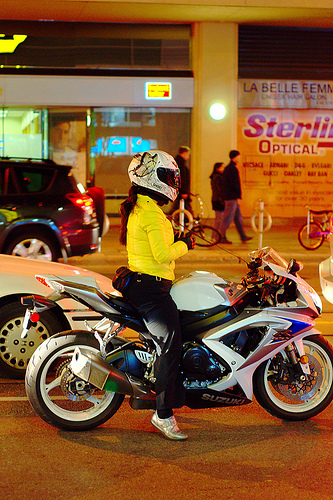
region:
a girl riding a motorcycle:
[96, 140, 233, 446]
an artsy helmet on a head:
[125, 146, 181, 199]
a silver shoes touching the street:
[145, 406, 193, 444]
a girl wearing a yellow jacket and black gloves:
[103, 144, 191, 445]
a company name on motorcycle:
[205, 390, 244, 407]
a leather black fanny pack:
[104, 266, 141, 290]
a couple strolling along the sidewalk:
[208, 141, 239, 237]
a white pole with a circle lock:
[254, 201, 273, 251]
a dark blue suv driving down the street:
[17, 157, 91, 254]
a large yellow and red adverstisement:
[243, 112, 322, 205]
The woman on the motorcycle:
[115, 149, 197, 440]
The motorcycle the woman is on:
[17, 244, 332, 432]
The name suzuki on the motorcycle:
[199, 389, 245, 408]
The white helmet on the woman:
[126, 147, 182, 202]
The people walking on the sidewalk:
[169, 143, 255, 247]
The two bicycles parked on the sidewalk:
[168, 193, 332, 249]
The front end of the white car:
[0, 249, 127, 378]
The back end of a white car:
[314, 223, 332, 306]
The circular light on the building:
[206, 102, 229, 120]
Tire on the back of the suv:
[86, 187, 109, 237]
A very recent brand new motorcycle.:
[18, 243, 332, 435]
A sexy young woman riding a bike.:
[111, 148, 195, 441]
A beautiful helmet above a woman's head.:
[126, 148, 181, 202]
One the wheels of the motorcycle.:
[24, 328, 129, 434]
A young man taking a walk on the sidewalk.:
[215, 147, 254, 244]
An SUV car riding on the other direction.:
[0, 154, 100, 262]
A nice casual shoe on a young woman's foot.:
[149, 410, 188, 442]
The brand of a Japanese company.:
[198, 391, 246, 405]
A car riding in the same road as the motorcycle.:
[0, 252, 124, 375]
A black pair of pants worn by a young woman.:
[124, 272, 183, 418]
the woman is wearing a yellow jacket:
[109, 193, 206, 296]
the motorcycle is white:
[175, 258, 322, 400]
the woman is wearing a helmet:
[124, 145, 203, 217]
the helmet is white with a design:
[127, 143, 192, 208]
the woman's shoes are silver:
[150, 409, 195, 453]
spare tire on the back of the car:
[75, 181, 122, 245]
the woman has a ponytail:
[112, 183, 135, 255]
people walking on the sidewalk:
[210, 138, 269, 262]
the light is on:
[196, 96, 242, 128]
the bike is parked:
[308, 205, 332, 258]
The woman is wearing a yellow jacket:
[116, 146, 200, 281]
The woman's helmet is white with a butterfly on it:
[123, 143, 187, 206]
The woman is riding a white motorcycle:
[22, 148, 332, 440]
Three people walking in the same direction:
[171, 142, 257, 246]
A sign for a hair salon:
[234, 76, 332, 113]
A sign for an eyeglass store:
[235, 105, 332, 215]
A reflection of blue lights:
[88, 129, 158, 159]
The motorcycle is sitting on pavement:
[17, 245, 332, 441]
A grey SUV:
[2, 153, 115, 262]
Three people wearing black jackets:
[169, 143, 247, 207]